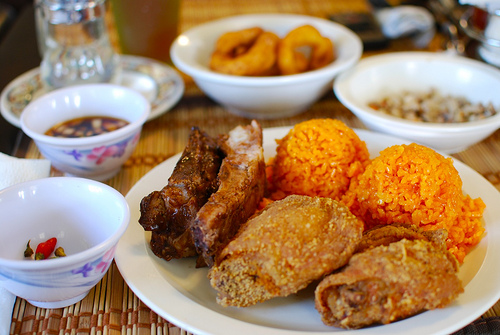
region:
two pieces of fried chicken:
[231, 216, 407, 333]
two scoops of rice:
[297, 110, 453, 252]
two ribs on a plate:
[147, 111, 255, 278]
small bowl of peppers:
[13, 211, 91, 302]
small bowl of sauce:
[34, 105, 130, 175]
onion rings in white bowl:
[202, 21, 322, 119]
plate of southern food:
[177, 120, 457, 324]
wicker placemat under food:
[24, 295, 111, 333]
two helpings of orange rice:
[281, 114, 457, 238]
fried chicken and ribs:
[177, 179, 391, 333]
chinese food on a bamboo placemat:
[7, 4, 488, 322]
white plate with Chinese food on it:
[118, 120, 493, 329]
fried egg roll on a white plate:
[316, 238, 463, 328]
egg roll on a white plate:
[198, 193, 365, 305]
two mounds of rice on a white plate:
[270, 120, 484, 253]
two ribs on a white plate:
[138, 120, 265, 266]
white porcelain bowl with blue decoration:
[0, 174, 132, 307]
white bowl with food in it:
[336, 48, 496, 155]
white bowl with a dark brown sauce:
[23, 79, 151, 186]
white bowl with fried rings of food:
[168, 13, 361, 117]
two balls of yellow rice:
[318, 123, 471, 238]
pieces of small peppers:
[17, 227, 77, 264]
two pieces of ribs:
[194, 152, 294, 214]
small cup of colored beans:
[389, 69, 479, 137]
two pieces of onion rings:
[183, 40, 328, 90]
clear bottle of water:
[31, 3, 121, 78]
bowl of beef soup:
[29, 104, 131, 146]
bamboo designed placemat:
[102, 303, 145, 320]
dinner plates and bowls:
[19, 89, 499, 259]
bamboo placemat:
[14, 121, 494, 331]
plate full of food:
[124, 123, 498, 329]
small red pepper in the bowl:
[31, 233, 56, 258]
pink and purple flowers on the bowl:
[4, 251, 118, 287]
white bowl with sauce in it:
[22, 83, 147, 167]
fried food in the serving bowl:
[210, 25, 332, 79]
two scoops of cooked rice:
[274, 117, 481, 248]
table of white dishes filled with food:
[0, 15, 497, 327]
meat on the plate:
[138, 122, 263, 264]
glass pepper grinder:
[40, 3, 110, 90]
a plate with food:
[122, 103, 493, 304]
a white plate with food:
[147, 84, 459, 286]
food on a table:
[182, 101, 445, 324]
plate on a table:
[161, 120, 493, 330]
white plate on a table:
[132, 98, 462, 333]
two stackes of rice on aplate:
[187, 43, 479, 333]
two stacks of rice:
[229, 95, 442, 322]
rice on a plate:
[197, 106, 459, 316]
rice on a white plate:
[182, 123, 454, 329]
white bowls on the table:
[16, 73, 254, 309]